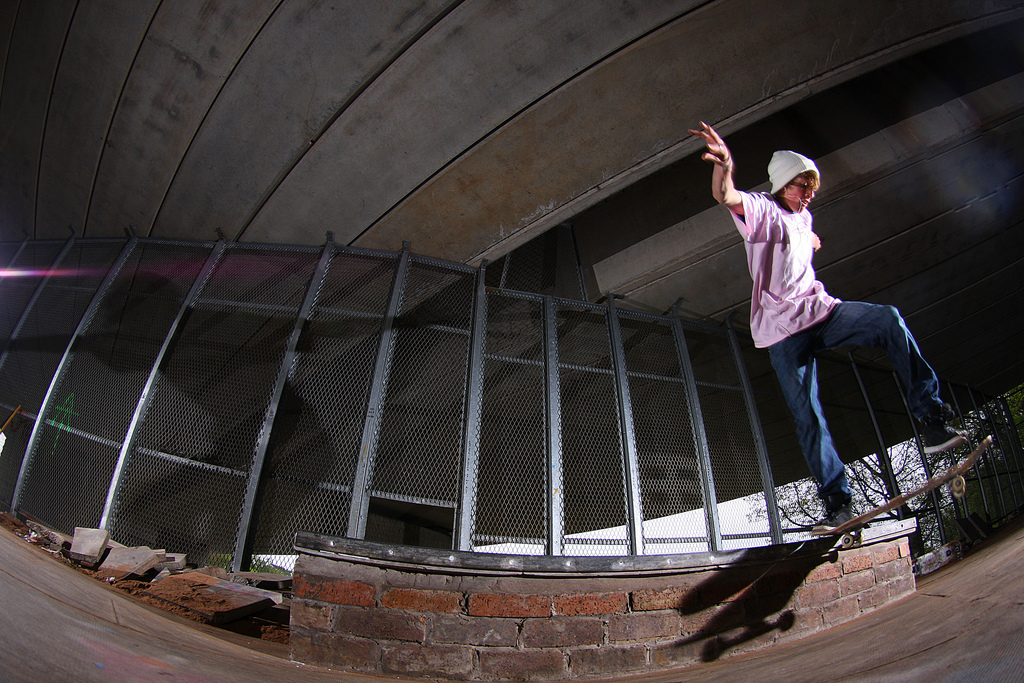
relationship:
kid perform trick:
[676, 119, 1024, 565] [650, 77, 1014, 557]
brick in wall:
[286, 552, 379, 607] [280, 541, 927, 678]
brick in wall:
[286, 552, 379, 607] [282, 515, 933, 671]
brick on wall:
[286, 552, 379, 607] [282, 515, 933, 671]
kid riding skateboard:
[676, 119, 1024, 565] [803, 440, 1017, 557]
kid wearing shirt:
[676, 119, 1024, 565] [714, 238, 875, 353]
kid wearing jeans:
[676, 119, 1024, 565] [751, 309, 950, 521]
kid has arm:
[676, 119, 1024, 565] [689, 201, 724, 219]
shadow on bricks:
[678, 513, 830, 665] [296, 547, 530, 668]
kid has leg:
[676, 119, 1024, 565] [747, 336, 847, 503]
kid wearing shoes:
[676, 119, 1024, 565] [790, 409, 968, 507]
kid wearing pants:
[676, 119, 1024, 565] [769, 301, 932, 509]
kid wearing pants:
[676, 119, 1024, 565] [773, 288, 946, 468]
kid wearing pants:
[676, 119, 1024, 565] [740, 299, 942, 481]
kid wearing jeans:
[676, 119, 1024, 565] [738, 284, 952, 514]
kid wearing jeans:
[676, 119, 1024, 565] [771, 294, 960, 500]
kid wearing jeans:
[676, 119, 1024, 565] [745, 281, 929, 504]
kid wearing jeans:
[676, 119, 1024, 565] [738, 294, 944, 493]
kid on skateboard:
[676, 119, 1024, 565] [762, 415, 994, 604]